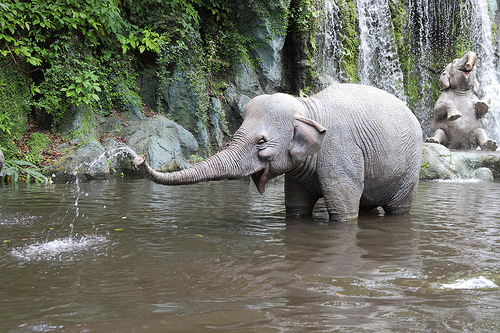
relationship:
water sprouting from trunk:
[73, 142, 140, 177] [146, 154, 251, 192]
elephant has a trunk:
[132, 82, 424, 222] [122, 141, 248, 188]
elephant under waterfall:
[423, 52, 497, 150] [407, 1, 487, 146]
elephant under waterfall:
[423, 52, 497, 150] [388, 11, 468, 81]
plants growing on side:
[120, 32, 177, 74] [5, 4, 322, 172]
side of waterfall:
[5, 4, 322, 172] [306, 7, 438, 102]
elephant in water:
[132, 82, 424, 222] [0, 171, 496, 329]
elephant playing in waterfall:
[132, 82, 424, 222] [305, 0, 493, 144]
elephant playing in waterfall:
[423, 52, 497, 150] [305, 0, 493, 144]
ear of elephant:
[287, 110, 328, 170] [128, 75, 426, 222]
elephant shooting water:
[128, 75, 426, 222] [8, 141, 143, 263]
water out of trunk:
[8, 141, 143, 263] [141, 137, 245, 183]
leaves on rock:
[46, 137, 78, 145] [39, 132, 137, 185]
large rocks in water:
[3, 33, 175, 183] [19, 221, 493, 330]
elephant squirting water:
[128, 75, 426, 222] [15, 145, 136, 258]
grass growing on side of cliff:
[383, 19, 466, 84] [3, 2, 223, 161]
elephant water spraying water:
[125, 86, 307, 210] [63, 142, 133, 234]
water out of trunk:
[63, 142, 133, 234] [127, 150, 250, 184]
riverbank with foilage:
[4, 112, 193, 179] [0, 112, 60, 184]